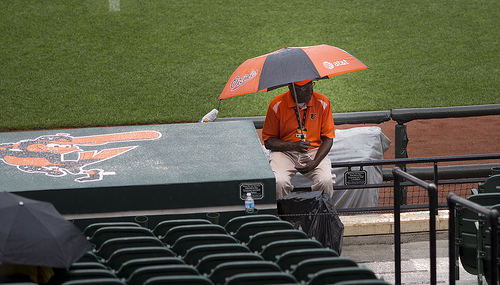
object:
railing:
[213, 102, 500, 210]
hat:
[294, 78, 316, 87]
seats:
[137, 275, 210, 285]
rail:
[392, 166, 439, 284]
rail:
[447, 192, 498, 284]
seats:
[64, 269, 119, 279]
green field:
[0, 0, 500, 131]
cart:
[276, 190, 343, 257]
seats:
[224, 273, 300, 283]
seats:
[452, 174, 498, 281]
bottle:
[201, 108, 219, 123]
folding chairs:
[91, 226, 155, 250]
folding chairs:
[451, 192, 500, 276]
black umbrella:
[1, 190, 93, 270]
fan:
[0, 263, 54, 283]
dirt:
[256, 115, 500, 204]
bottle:
[245, 192, 255, 213]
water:
[245, 199, 255, 213]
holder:
[245, 208, 259, 215]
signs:
[344, 170, 368, 186]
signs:
[239, 183, 264, 201]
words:
[354, 175, 357, 177]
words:
[357, 178, 360, 180]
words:
[256, 189, 261, 192]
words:
[243, 189, 246, 193]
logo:
[0, 129, 164, 183]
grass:
[384, 26, 449, 96]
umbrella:
[217, 44, 369, 99]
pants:
[267, 146, 334, 201]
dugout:
[0, 119, 280, 229]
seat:
[229, 212, 282, 227]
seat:
[233, 220, 296, 234]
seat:
[243, 229, 308, 246]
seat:
[274, 247, 339, 267]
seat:
[182, 241, 251, 257]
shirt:
[261, 90, 335, 152]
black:
[17, 201, 64, 261]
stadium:
[0, 0, 500, 285]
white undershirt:
[296, 103, 304, 109]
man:
[262, 79, 336, 201]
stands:
[0, 213, 392, 285]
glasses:
[294, 81, 316, 91]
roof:
[1, 118, 278, 193]